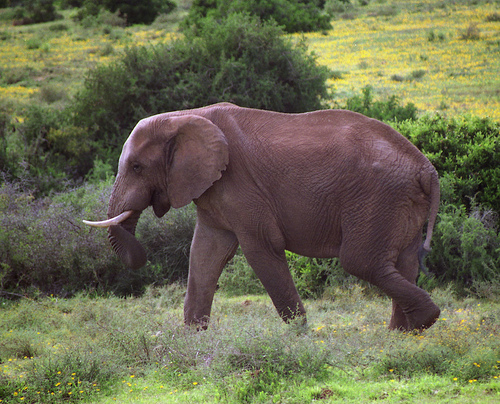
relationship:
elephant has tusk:
[81, 100, 445, 336] [79, 210, 133, 231]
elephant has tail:
[81, 100, 445, 336] [422, 161, 438, 253]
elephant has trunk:
[81, 100, 445, 336] [109, 177, 151, 270]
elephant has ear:
[81, 100, 445, 336] [155, 115, 230, 220]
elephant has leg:
[81, 100, 445, 336] [224, 199, 309, 339]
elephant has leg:
[81, 100, 445, 336] [182, 211, 237, 330]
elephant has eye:
[81, 100, 445, 336] [131, 162, 142, 172]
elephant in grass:
[81, 100, 445, 336] [1, 0, 499, 402]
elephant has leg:
[81, 100, 445, 336] [338, 198, 442, 334]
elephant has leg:
[81, 100, 445, 336] [391, 226, 424, 335]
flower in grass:
[128, 373, 137, 379] [1, 0, 499, 402]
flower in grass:
[71, 372, 77, 377] [1, 0, 499, 402]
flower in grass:
[57, 371, 62, 376] [1, 0, 499, 402]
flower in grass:
[389, 368, 394, 372] [1, 0, 499, 402]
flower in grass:
[453, 378, 457, 382] [1, 0, 499, 402]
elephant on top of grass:
[81, 100, 445, 336] [1, 0, 499, 402]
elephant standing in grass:
[81, 100, 445, 336] [1, 0, 499, 402]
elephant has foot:
[81, 100, 445, 336] [178, 324, 208, 335]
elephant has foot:
[81, 100, 445, 336] [284, 325, 310, 337]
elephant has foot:
[81, 100, 445, 336] [409, 307, 440, 329]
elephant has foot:
[81, 100, 445, 336] [391, 322, 414, 334]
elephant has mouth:
[81, 100, 445, 336] [135, 189, 167, 217]